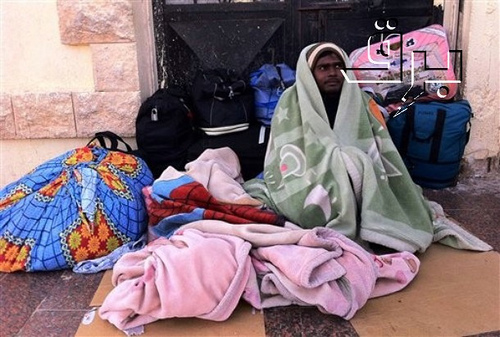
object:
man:
[262, 40, 489, 252]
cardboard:
[354, 245, 500, 336]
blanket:
[241, 41, 496, 255]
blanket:
[99, 217, 420, 335]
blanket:
[2, 144, 153, 275]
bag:
[133, 88, 193, 165]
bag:
[249, 62, 297, 126]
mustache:
[323, 78, 340, 84]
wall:
[1, 0, 150, 187]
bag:
[383, 97, 474, 190]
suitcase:
[348, 23, 461, 110]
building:
[0, 0, 500, 204]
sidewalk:
[2, 187, 496, 335]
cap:
[304, 44, 349, 72]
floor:
[2, 274, 78, 336]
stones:
[57, 0, 138, 45]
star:
[272, 105, 291, 125]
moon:
[301, 185, 334, 223]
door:
[156, 3, 446, 93]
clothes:
[72, 237, 148, 276]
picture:
[1, 5, 495, 335]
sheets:
[158, 148, 259, 207]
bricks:
[13, 91, 77, 138]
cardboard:
[70, 255, 265, 335]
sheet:
[141, 176, 282, 235]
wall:
[454, 3, 499, 160]